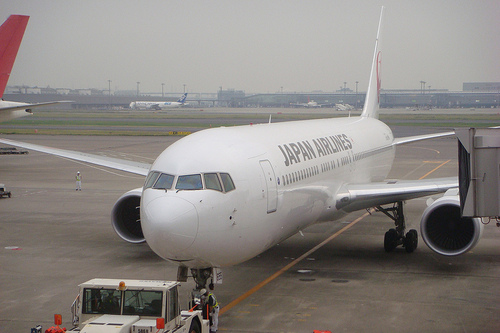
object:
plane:
[0, 0, 500, 258]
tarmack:
[0, 126, 499, 332]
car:
[28, 276, 219, 333]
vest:
[202, 291, 220, 309]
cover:
[41, 312, 66, 333]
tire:
[382, 228, 398, 252]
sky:
[1, 1, 500, 91]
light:
[117, 280, 123, 288]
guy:
[199, 289, 216, 328]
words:
[278, 133, 353, 167]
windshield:
[143, 169, 237, 194]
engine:
[418, 195, 482, 257]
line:
[216, 157, 453, 316]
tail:
[1, 14, 74, 122]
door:
[260, 160, 278, 214]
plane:
[128, 92, 189, 111]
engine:
[109, 188, 147, 245]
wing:
[0, 138, 152, 178]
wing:
[319, 178, 461, 224]